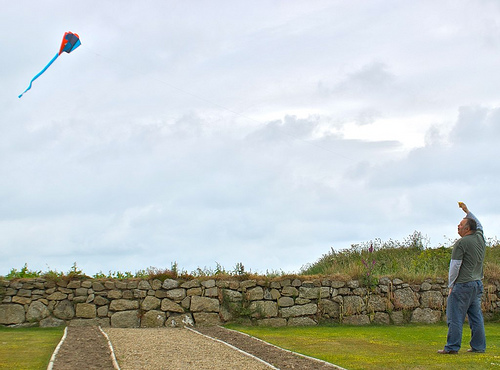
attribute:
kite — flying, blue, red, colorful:
[11, 30, 82, 100]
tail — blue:
[17, 49, 67, 98]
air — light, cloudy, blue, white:
[0, 1, 496, 275]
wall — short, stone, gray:
[1, 275, 498, 325]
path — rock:
[46, 327, 350, 369]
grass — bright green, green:
[1, 326, 67, 369]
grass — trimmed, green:
[219, 322, 498, 368]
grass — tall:
[313, 248, 497, 277]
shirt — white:
[446, 259, 462, 290]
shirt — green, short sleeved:
[451, 232, 487, 284]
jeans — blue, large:
[446, 277, 487, 354]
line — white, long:
[94, 326, 119, 369]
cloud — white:
[374, 110, 500, 177]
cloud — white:
[320, 62, 427, 123]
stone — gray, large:
[339, 294, 365, 318]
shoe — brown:
[436, 348, 459, 355]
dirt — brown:
[49, 322, 115, 369]